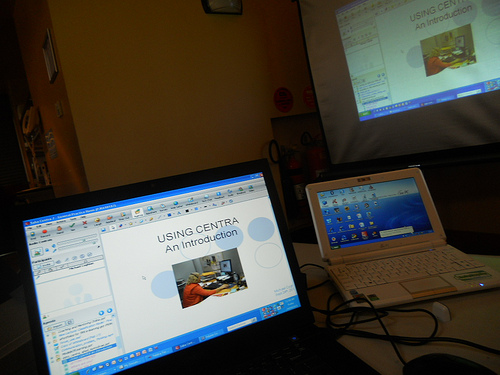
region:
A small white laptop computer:
[298, 168, 498, 306]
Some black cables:
[285, 256, 498, 366]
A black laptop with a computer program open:
[13, 173, 389, 374]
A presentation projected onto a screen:
[314, 1, 496, 160]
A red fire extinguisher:
[263, 133, 312, 243]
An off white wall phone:
[15, 101, 48, 154]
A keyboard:
[322, 254, 485, 286]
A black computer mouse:
[391, 343, 496, 374]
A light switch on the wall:
[50, 96, 70, 125]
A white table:
[279, 233, 499, 371]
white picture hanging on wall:
[34, 25, 63, 90]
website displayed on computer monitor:
[23, 172, 298, 354]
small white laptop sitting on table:
[294, 169, 498, 311]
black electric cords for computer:
[332, 303, 445, 349]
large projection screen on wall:
[289, 0, 497, 167]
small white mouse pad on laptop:
[384, 272, 462, 297]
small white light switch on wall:
[46, 94, 74, 136]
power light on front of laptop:
[472, 276, 492, 296]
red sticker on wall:
[250, 70, 303, 116]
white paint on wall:
[116, 55, 232, 150]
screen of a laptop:
[38, 165, 287, 369]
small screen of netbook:
[309, 167, 439, 253]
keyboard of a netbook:
[343, 247, 460, 290]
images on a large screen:
[346, 0, 491, 124]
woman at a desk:
[181, 274, 223, 301]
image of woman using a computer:
[159, 248, 246, 314]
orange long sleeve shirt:
[173, 285, 228, 310]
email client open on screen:
[38, 182, 258, 365]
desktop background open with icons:
[308, 180, 417, 259]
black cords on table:
[311, 306, 472, 367]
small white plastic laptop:
[308, 165, 497, 316]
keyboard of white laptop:
[335, 253, 479, 286]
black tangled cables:
[294, 260, 469, 365]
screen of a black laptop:
[8, 155, 283, 369]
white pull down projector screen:
[300, 5, 498, 167]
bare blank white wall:
[73, 4, 242, 142]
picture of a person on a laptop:
[167, 250, 258, 310]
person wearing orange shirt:
[180, 280, 219, 303]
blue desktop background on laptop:
[320, 185, 428, 246]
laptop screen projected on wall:
[337, 5, 498, 128]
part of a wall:
[192, 85, 220, 116]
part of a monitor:
[147, 259, 179, 301]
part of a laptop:
[205, 235, 242, 279]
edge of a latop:
[5, 267, 53, 322]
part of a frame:
[156, 246, 210, 323]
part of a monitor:
[350, 192, 379, 231]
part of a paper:
[323, 287, 368, 345]